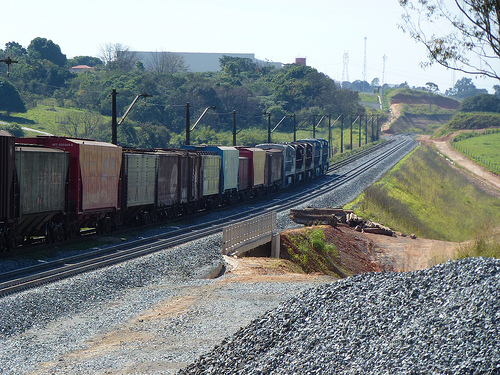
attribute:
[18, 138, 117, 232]
freight car — orange, moving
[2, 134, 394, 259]
track — occupied, narrow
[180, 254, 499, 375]
pile — gravel, large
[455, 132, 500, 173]
field — fenced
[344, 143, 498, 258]
slope — grassy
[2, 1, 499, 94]
sky — hazy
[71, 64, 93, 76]
building — white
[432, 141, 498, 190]
road — dirt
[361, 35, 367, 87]
tower — metal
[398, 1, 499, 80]
tree — green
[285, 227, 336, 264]
grass — green